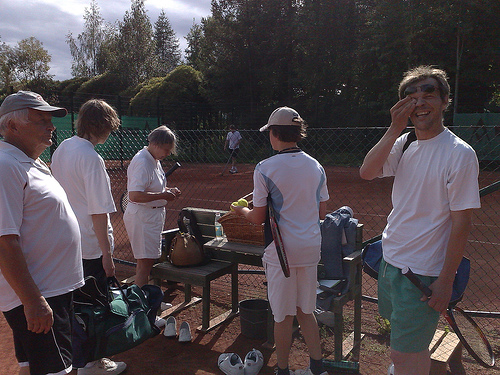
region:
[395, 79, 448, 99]
Black sunglasses on man's forehead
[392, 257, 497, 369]
Tennis racket in man's hand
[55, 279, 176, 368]
Blue and green bag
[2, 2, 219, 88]
White and gray cloudy skies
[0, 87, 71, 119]
Man's gray baseball cap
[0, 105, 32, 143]
Man's white hair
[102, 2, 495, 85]
Green trees in distance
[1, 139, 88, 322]
Man's white polo shirt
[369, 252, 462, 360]
Man's green shorts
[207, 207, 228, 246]
Bottle of water on table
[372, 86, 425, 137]
Man's hand on his eye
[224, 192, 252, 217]
Two green tennis balls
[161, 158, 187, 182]
Handle of tennis racket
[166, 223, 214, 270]
Brown bag on table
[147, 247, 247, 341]
Brown wooden table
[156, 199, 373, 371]
Brown wooden bench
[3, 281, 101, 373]
Man's black and white shorts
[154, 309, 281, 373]
Tennis shoes sitting on the ground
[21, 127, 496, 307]
Metal chain link fence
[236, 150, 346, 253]
Person's blue and white shirt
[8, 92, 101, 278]
man wearing gray hat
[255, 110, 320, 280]
man wearing tan hat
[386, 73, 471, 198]
man wearing sun glasses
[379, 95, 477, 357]
man carrying blue bag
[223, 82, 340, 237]
man holding tennis balls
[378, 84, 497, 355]
man holding tennis racket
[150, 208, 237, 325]
tan bag sitting on table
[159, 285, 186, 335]
white shoes under table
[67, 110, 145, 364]
man carrying green bag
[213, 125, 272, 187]
man playing tennis in court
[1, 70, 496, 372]
several people getting ready to play tennis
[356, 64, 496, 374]
man is holding tennis racket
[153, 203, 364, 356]
bench is covered with people's stuff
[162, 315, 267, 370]
empty white athletic shoe pairs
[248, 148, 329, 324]
person is wearing white and blue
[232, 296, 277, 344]
bucket under the bench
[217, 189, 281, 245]
wooden basket between the people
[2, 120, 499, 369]
chain link fence behind people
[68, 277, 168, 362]
person is holding green bag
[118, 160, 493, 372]
three tennis rackets being held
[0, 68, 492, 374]
a group of people standing around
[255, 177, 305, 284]
a racket held under arm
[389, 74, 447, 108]
sunglasses on his forehead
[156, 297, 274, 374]
two pairs of white shoes on the ground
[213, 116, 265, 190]
one man on the tennis court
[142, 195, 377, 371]
a bench filled with stuff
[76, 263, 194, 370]
a green and black duffle bag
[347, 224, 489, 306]
a blue and black duffle bag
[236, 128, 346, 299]
a white shirt with blue parts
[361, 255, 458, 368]
green shorts on man